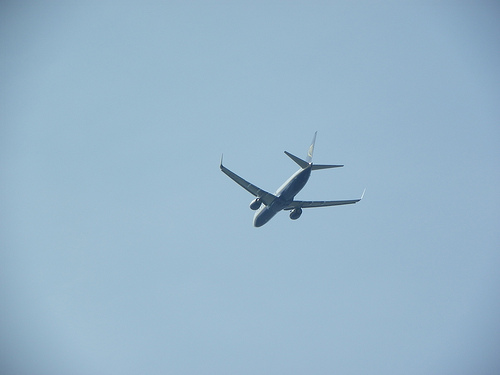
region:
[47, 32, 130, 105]
section of blue sky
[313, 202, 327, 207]
part of a right wing of a aeroplane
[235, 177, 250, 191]
left wing of an aeroplane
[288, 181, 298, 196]
bottom part of an aeroplane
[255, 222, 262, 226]
front part of an aeroplane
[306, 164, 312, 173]
back part of an aeroplane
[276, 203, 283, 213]
wheels of an aeroplane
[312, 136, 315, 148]
upper most part of an aeroplane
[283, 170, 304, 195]
section of an aeroplanes boday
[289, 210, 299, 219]
right fan of an aeroplane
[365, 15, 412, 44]
part of the sky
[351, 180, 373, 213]
edge of the right wing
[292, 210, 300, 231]
part of the right engine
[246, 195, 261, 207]
part of a left engine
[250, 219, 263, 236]
tip of a plane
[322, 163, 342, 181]
part of a right hind wing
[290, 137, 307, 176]
part of a left hind wing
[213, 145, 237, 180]
edge of a left wing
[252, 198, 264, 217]
part of the left engine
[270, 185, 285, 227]
bottom of the plane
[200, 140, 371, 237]
this is a plane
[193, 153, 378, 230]
the plane is white in color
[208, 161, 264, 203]
this is left wing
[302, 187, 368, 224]
this is right wing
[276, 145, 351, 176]
this is the tail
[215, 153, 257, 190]
the wing is sharp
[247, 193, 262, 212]
this is the propeller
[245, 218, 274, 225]
the head is streamlined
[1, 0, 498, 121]
the sky is blue in color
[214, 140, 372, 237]
the plane is big in size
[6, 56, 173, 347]
this is the sky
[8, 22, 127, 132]
the sky is blue in color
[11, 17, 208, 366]
the sky is clear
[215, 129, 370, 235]
this is an aircraft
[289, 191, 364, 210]
this is the airplane's wing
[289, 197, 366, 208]
the wing is long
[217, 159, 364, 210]
the airplane has two wings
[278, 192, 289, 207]
the airplane is white in color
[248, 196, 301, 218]
the airplane has two propellers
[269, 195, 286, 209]
the airplane is metallic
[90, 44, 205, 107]
this is the sky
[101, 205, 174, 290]
the sky is blue in color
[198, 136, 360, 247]
the plane is fying in the sky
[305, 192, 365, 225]
this are wings of a plane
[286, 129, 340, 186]
this is the tail of the plane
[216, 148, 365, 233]
the plane is blue in color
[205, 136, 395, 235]
the plane is small in size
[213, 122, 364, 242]
the plane is made of metal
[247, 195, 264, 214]
this is the plane propeller